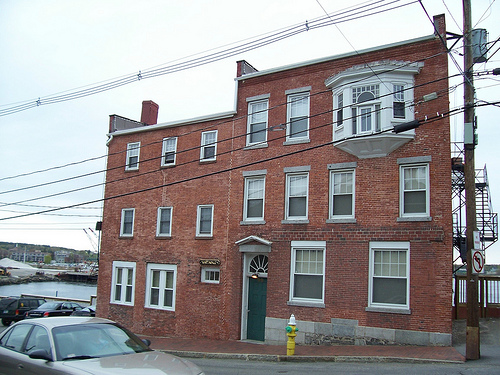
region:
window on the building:
[286, 177, 308, 235]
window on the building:
[283, 241, 320, 300]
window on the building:
[383, 252, 403, 306]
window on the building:
[142, 272, 181, 305]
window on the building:
[195, 206, 214, 238]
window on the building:
[153, 209, 174, 236]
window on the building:
[123, 215, 135, 237]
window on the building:
[103, 272, 133, 308]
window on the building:
[163, 134, 173, 168]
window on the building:
[124, 147, 142, 175]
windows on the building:
[92, 58, 469, 353]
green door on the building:
[241, 273, 266, 338]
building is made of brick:
[86, 14, 476, 349]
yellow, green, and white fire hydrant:
[278, 309, 303, 356]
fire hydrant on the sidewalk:
[277, 308, 303, 355]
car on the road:
[0, 317, 206, 374]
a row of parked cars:
[0, 290, 115, 326]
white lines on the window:
[373, 248, 410, 278]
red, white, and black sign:
[471, 249, 488, 274]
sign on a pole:
[468, 224, 485, 249]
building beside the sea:
[27, 82, 175, 371]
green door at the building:
[230, 253, 281, 353]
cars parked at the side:
[2, 279, 193, 374]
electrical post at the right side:
[455, 116, 494, 213]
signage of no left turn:
[463, 244, 488, 289]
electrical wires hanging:
[21, 149, 91, 250]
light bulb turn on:
[248, 272, 262, 282]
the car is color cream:
[20, 322, 200, 373]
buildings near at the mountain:
[2, 233, 88, 290]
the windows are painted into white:
[287, 237, 332, 314]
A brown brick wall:
[326, 244, 364, 306]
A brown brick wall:
[176, 299, 245, 331]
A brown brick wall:
[415, 252, 451, 330]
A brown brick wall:
[133, 307, 196, 332]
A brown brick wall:
[170, 202, 197, 278]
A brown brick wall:
[356, 178, 394, 228]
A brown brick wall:
[109, 174, 160, 204]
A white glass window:
[361, 235, 410, 312]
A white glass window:
[291, 242, 326, 307]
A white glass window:
[147, 258, 177, 323]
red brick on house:
[113, 99, 458, 349]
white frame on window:
[281, 237, 327, 306]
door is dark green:
[235, 258, 263, 345]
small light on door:
[248, 269, 260, 282]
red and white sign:
[465, 245, 495, 277]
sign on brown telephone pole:
[426, 13, 486, 370]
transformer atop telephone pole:
[463, 23, 485, 66]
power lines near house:
[90, 9, 280, 190]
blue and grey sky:
[12, 9, 123, 109]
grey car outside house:
[16, 306, 173, 374]